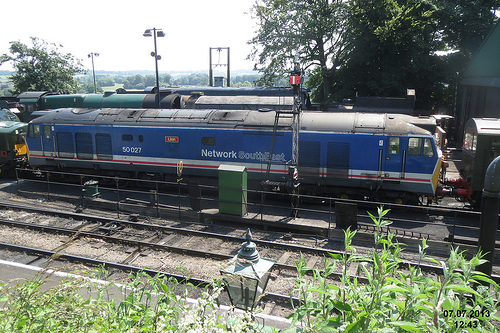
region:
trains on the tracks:
[13, 85, 466, 220]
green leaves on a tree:
[306, 232, 478, 325]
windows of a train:
[52, 127, 111, 164]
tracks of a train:
[11, 182, 210, 292]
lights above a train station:
[141, 23, 173, 85]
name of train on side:
[196, 139, 297, 172]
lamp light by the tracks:
[216, 231, 271, 316]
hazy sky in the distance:
[45, 5, 127, 47]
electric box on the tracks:
[211, 157, 252, 235]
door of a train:
[374, 130, 405, 187]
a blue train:
[17, 103, 437, 199]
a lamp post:
[224, 244, 267, 310]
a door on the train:
[381, 135, 403, 172]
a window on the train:
[31, 123, 48, 134]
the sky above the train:
[31, 1, 241, 60]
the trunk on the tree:
[314, 35, 331, 100]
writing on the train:
[199, 146, 293, 162]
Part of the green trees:
[38, 311, 91, 323]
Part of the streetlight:
[143, 29, 150, 35]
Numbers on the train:
[118, 142, 143, 157]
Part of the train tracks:
[21, 247, 41, 254]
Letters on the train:
[198, 145, 240, 159]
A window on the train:
[91, 131, 116, 163]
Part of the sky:
[97, 31, 127, 46]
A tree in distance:
[121, 73, 146, 90]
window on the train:
[57, 131, 75, 161]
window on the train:
[75, 132, 92, 159]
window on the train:
[92, 133, 114, 161]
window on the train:
[297, 141, 319, 181]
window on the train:
[389, 137, 397, 159]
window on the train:
[405, 132, 420, 157]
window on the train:
[407, 135, 424, 160]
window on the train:
[425, 137, 434, 157]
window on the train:
[30, 123, 42, 137]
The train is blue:
[10, 85, 467, 270]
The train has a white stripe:
[15, 93, 469, 220]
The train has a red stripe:
[13, 84, 456, 248]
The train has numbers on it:
[22, 88, 470, 223]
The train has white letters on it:
[17, 86, 442, 234]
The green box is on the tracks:
[180, 151, 303, 250]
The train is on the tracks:
[6, 70, 451, 240]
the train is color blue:
[17, 92, 450, 212]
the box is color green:
[208, 156, 258, 224]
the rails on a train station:
[13, 166, 491, 310]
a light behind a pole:
[138, 23, 176, 105]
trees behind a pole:
[242, 1, 493, 138]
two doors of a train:
[290, 134, 355, 196]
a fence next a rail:
[21, 168, 223, 245]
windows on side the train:
[114, 128, 224, 148]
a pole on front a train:
[286, 55, 311, 220]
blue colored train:
[22, 103, 454, 208]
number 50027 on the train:
[121, 143, 145, 154]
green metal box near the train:
[213, 158, 255, 221]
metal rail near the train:
[11, 165, 495, 247]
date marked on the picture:
[443, 300, 493, 329]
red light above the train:
[287, 66, 302, 91]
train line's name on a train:
[199, 146, 288, 166]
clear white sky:
[1, 12, 264, 78]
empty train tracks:
[0, 196, 496, 326]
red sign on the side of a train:
[160, 131, 183, 146]